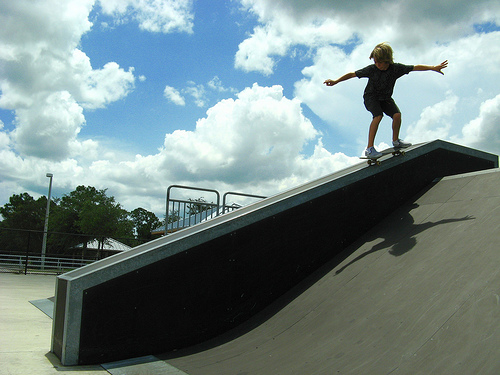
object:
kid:
[324, 43, 449, 159]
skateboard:
[360, 143, 412, 165]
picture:
[0, 0, 500, 375]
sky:
[0, 2, 499, 230]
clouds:
[1, 1, 137, 162]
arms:
[335, 65, 372, 84]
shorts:
[364, 97, 401, 118]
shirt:
[355, 63, 414, 100]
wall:
[80, 150, 442, 366]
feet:
[365, 147, 382, 158]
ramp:
[153, 170, 500, 374]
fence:
[0, 254, 100, 274]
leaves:
[81, 208, 120, 234]